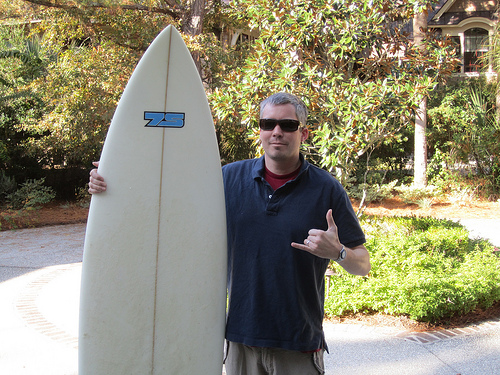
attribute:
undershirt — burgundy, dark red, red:
[262, 161, 303, 191]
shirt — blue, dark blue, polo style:
[222, 152, 366, 355]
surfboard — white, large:
[80, 23, 227, 374]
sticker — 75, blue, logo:
[143, 112, 186, 127]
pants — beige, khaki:
[223, 337, 325, 375]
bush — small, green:
[324, 214, 499, 323]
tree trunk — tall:
[413, 4, 428, 189]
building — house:
[367, 0, 499, 174]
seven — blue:
[143, 110, 166, 128]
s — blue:
[158, 113, 183, 127]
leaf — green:
[319, 138, 326, 152]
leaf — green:
[477, 81, 482, 105]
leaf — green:
[377, 13, 388, 25]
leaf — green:
[221, 111, 228, 121]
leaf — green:
[325, 70, 331, 79]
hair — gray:
[258, 91, 310, 130]